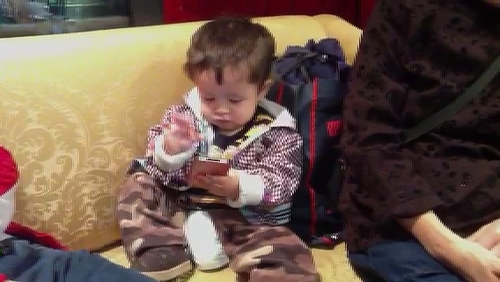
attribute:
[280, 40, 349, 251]
bag — blue, red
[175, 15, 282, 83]
hair — brown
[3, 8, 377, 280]
couch — yellow,  floral pattern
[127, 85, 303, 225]
coat — brown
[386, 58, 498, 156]
strap — black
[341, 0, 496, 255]
shirt — brown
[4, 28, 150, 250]
couch — yellow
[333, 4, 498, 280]
person — brown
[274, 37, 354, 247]
backpack — blue , red 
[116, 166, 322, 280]
pants — camouflage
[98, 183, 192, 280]
camo — brown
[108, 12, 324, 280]
child — looking down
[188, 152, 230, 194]
phone — pink 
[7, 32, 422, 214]
sofa — yellow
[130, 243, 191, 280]
shoe — black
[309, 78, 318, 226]
line — red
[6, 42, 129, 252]
print — paisley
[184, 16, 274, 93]
hair — dark brown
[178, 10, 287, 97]
hair — brown